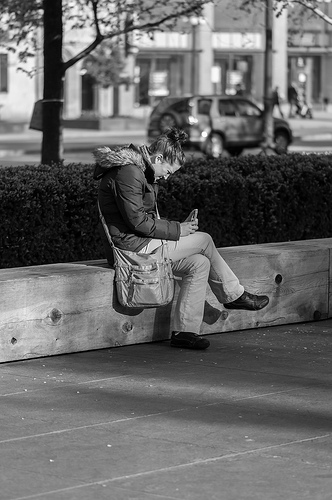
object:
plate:
[185, 208, 198, 234]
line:
[41, 98, 65, 103]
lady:
[91, 126, 270, 350]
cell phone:
[191, 209, 199, 234]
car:
[158, 94, 293, 159]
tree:
[0, 0, 220, 165]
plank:
[0, 235, 330, 364]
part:
[209, 448, 249, 462]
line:
[10, 434, 332, 500]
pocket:
[129, 264, 164, 304]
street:
[66, 141, 96, 160]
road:
[7, 140, 330, 154]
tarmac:
[0, 118, 332, 155]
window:
[217, 98, 263, 117]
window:
[197, 98, 212, 116]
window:
[150, 97, 191, 119]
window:
[0, 53, 9, 93]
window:
[79, 71, 96, 112]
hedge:
[240, 149, 332, 245]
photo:
[0, 1, 330, 500]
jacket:
[92, 142, 181, 253]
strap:
[97, 183, 166, 247]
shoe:
[223, 290, 269, 311]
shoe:
[170, 331, 211, 350]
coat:
[92, 142, 181, 268]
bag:
[98, 198, 175, 309]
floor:
[0, 313, 330, 497]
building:
[131, 0, 331, 119]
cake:
[184, 209, 198, 227]